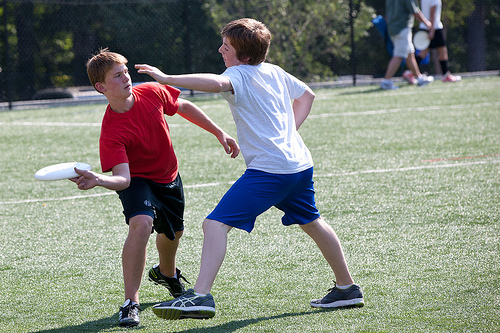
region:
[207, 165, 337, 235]
white car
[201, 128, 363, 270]
white car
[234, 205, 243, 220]
the short is blue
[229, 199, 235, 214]
the short is blue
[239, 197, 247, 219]
the short is blue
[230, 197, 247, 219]
the short is blue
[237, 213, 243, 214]
the short is blue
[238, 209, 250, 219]
the short is blue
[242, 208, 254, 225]
the short is blue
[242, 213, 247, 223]
the short is blue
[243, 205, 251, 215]
the short is blue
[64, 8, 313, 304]
these are two players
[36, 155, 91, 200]
this is a plate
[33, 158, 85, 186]
the plate is white in color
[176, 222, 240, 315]
the leg is up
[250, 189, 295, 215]
the short is blue in color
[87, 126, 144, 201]
the hand is bent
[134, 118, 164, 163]
the t shirt is red in color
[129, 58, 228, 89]
the hand is apart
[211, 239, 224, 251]
the boy is light skinned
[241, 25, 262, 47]
the hair is short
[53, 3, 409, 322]
two kids playing the disk game in the ground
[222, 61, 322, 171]
the white color t shirt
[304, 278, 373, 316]
the grey color shoe of the player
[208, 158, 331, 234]
the blue color shorts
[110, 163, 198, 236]
the black color short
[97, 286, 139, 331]
the black color shoe of the player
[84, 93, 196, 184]
the red color t shirt of the player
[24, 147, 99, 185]
the white color disk used to play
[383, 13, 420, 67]
the white color short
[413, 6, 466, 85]
the man with disk in hand walking in the ground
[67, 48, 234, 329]
boy in the red shirt playing frisbee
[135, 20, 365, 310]
boy in the white shirt playing frisbee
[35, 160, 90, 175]
white frisbee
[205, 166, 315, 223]
blue athletic shorts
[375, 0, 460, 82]
two people walking together in the distance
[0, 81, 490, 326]
green athletic field with white stripes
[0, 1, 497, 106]
black chain-link fence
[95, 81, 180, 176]
red t-shirt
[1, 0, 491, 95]
trees beyond the fence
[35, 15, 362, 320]
two boys playing ultimate frisbee